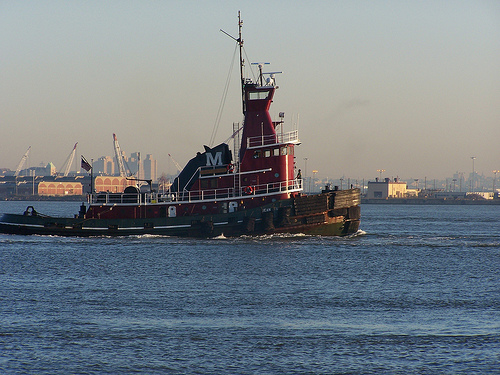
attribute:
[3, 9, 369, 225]
ship — big, red, black, moving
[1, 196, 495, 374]
ocean — blue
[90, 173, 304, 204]
rails — white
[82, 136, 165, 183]
buildings — in background, tall, large, white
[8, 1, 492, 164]
sky — blue, cloudy, grey, clear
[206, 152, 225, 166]
m — white, large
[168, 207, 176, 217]
door — white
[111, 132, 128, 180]
crane — white, in distance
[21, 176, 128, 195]
buildings — red, tan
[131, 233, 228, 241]
foam — white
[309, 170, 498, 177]
lights — tall